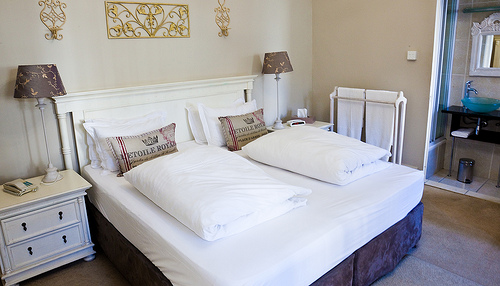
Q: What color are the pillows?
A: White.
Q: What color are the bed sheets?
A: White.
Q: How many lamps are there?
A: Two.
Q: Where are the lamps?
A: On the nightstands.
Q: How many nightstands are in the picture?
A: Two.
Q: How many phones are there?
A: One.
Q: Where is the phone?
A: On the nightstand.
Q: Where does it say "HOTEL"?
A: On the pillows.